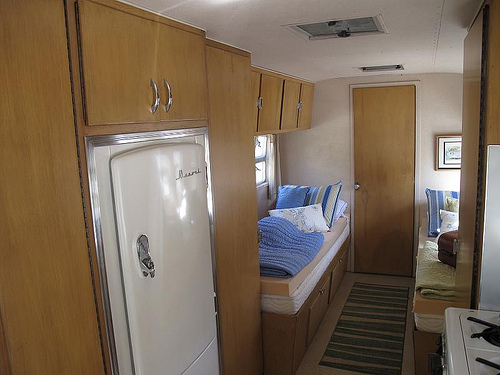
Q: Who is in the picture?
A: Nobody.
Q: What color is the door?
A: Brown.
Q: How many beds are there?
A: Two.